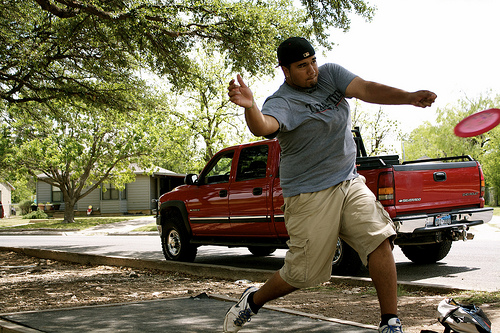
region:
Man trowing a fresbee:
[210, 12, 445, 327]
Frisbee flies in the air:
[440, 90, 495, 150]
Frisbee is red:
[445, 99, 498, 140]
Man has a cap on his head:
[173, 20, 449, 330]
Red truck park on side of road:
[120, 125, 496, 286]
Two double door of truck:
[141, 133, 276, 260]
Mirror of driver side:
[173, 165, 203, 195]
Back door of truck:
[381, 147, 491, 219]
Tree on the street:
[5, 46, 195, 227]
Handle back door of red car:
[429, 169, 454, 182]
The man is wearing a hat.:
[260, 28, 322, 103]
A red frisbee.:
[445, 85, 495, 155]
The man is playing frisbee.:
[201, 25, 433, 330]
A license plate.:
[425, 206, 455, 233]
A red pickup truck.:
[135, 135, 495, 265]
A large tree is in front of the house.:
[0, 80, 195, 215]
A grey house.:
[30, 167, 170, 218]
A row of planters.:
[25, 200, 60, 215]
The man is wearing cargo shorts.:
[265, 155, 410, 320]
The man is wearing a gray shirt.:
[241, 35, 371, 190]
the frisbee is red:
[452, 96, 499, 143]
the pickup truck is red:
[155, 140, 494, 272]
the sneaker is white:
[211, 281, 265, 331]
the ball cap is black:
[268, 35, 320, 71]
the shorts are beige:
[277, 178, 401, 287]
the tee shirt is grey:
[261, 58, 363, 198]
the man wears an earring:
[282, 74, 290, 81]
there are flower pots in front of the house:
[28, 197, 63, 212]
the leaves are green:
[2, 2, 381, 122]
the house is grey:
[31, 157, 181, 223]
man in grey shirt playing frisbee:
[225, 35, 436, 331]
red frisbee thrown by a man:
[451, 107, 499, 139]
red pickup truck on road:
[153, 137, 496, 264]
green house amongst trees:
[31, 160, 186, 218]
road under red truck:
[0, 228, 499, 288]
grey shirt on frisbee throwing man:
[260, 63, 361, 195]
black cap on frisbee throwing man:
[277, 35, 315, 66]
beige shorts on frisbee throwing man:
[277, 176, 396, 290]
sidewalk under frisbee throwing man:
[1, 288, 380, 331]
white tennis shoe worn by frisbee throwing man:
[223, 285, 258, 331]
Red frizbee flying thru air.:
[445, 93, 496, 155]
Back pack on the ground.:
[410, 265, 483, 331]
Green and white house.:
[48, 146, 169, 233]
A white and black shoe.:
[220, 278, 265, 330]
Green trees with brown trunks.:
[6, 83, 141, 221]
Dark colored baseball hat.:
[260, 27, 332, 71]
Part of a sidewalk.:
[23, 288, 195, 329]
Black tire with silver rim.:
[142, 217, 204, 263]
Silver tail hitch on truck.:
[437, 221, 487, 253]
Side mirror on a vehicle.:
[170, 155, 215, 199]